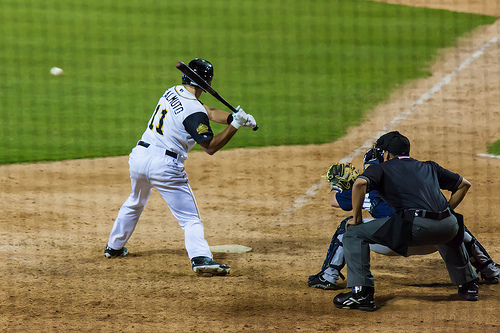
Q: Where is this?
A: This is at the field.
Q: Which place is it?
A: It is a field.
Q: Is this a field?
A: Yes, it is a field.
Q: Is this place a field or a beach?
A: It is a field.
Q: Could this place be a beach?
A: No, it is a field.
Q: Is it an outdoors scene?
A: Yes, it is outdoors.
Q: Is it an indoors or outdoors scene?
A: It is outdoors.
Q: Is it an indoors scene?
A: No, it is outdoors.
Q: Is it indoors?
A: No, it is outdoors.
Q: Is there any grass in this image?
A: Yes, there is grass.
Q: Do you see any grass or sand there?
A: Yes, there is grass.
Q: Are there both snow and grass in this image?
A: No, there is grass but no snow.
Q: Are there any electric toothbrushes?
A: No, there are no electric toothbrushes.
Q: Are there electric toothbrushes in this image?
A: No, there are no electric toothbrushes.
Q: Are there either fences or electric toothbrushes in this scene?
A: No, there are no electric toothbrushes or fences.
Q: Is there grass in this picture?
A: Yes, there is grass.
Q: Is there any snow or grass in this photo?
A: Yes, there is grass.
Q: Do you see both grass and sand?
A: No, there is grass but no sand.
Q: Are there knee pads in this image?
A: No, there are no knee pads.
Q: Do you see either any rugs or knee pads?
A: No, there are no knee pads or rugs.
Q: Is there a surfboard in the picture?
A: No, there are no surfboards.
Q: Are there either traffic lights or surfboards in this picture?
A: No, there are no surfboards or traffic lights.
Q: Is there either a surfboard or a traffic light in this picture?
A: No, there are no surfboards or traffic lights.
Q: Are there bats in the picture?
A: Yes, there is a bat.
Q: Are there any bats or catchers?
A: Yes, there is a bat.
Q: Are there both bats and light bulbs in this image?
A: No, there is a bat but no light bulbs.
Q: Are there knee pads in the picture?
A: No, there are no knee pads.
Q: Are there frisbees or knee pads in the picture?
A: No, there are no knee pads or frisbees.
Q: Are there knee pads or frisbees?
A: No, there are no knee pads or frisbees.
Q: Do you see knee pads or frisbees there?
A: No, there are no knee pads or frisbees.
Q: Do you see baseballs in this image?
A: Yes, there is a baseball.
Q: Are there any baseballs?
A: Yes, there is a baseball.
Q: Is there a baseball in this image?
A: Yes, there is a baseball.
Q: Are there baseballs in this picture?
A: Yes, there is a baseball.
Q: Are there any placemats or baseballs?
A: Yes, there is a baseball.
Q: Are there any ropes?
A: No, there are no ropes.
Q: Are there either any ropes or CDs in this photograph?
A: No, there are no ropes or cds.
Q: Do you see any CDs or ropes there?
A: No, there are no ropes or cds.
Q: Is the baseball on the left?
A: Yes, the baseball is on the left of the image.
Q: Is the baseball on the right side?
A: No, the baseball is on the left of the image.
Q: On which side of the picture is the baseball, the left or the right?
A: The baseball is on the left of the image.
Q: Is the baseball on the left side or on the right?
A: The baseball is on the left of the image.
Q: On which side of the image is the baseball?
A: The baseball is on the left of the image.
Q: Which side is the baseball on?
A: The baseball is on the left of the image.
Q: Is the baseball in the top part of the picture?
A: Yes, the baseball is in the top of the image.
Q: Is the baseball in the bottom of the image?
A: No, the baseball is in the top of the image.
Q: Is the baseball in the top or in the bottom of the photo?
A: The baseball is in the top of the image.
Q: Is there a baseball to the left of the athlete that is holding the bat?
A: Yes, there is a baseball to the left of the athlete.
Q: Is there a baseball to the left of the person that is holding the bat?
A: Yes, there is a baseball to the left of the athlete.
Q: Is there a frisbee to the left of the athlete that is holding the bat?
A: No, there is a baseball to the left of the athlete.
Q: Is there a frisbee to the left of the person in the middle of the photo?
A: No, there is a baseball to the left of the athlete.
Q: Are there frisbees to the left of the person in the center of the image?
A: No, there is a baseball to the left of the athlete.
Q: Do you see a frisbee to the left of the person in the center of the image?
A: No, there is a baseball to the left of the athlete.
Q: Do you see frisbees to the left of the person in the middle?
A: No, there is a baseball to the left of the athlete.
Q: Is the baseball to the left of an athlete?
A: Yes, the baseball is to the left of an athlete.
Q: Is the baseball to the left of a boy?
A: No, the baseball is to the left of an athlete.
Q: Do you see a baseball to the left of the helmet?
A: Yes, there is a baseball to the left of the helmet.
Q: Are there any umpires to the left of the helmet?
A: No, there is a baseball to the left of the helmet.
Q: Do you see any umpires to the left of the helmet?
A: No, there is a baseball to the left of the helmet.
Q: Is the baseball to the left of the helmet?
A: Yes, the baseball is to the left of the helmet.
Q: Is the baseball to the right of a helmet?
A: No, the baseball is to the left of a helmet.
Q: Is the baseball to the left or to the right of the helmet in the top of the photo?
A: The baseball is to the left of the helmet.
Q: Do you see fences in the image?
A: No, there are no fences.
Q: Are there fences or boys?
A: No, there are no fences or boys.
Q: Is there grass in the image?
A: Yes, there is grass.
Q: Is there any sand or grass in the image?
A: Yes, there is grass.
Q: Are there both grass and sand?
A: No, there is grass but no sand.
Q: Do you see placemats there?
A: No, there are no placemats.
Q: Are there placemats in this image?
A: No, there are no placemats.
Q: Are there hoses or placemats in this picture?
A: No, there are no placemats or hoses.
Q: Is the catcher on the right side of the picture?
A: Yes, the catcher is on the right of the image.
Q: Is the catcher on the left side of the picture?
A: No, the catcher is on the right of the image.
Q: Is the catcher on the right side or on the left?
A: The catcher is on the right of the image.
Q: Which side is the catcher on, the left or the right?
A: The catcher is on the right of the image.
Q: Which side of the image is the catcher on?
A: The catcher is on the right of the image.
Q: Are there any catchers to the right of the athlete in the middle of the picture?
A: Yes, there is a catcher to the right of the athlete.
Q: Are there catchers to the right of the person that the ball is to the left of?
A: Yes, there is a catcher to the right of the athlete.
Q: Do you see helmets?
A: Yes, there is a helmet.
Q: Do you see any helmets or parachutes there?
A: Yes, there is a helmet.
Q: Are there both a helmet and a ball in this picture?
A: Yes, there are both a helmet and a ball.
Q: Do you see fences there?
A: No, there are no fences.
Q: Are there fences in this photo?
A: No, there are no fences.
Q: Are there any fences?
A: No, there are no fences.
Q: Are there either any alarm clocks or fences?
A: No, there are no fences or alarm clocks.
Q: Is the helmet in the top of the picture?
A: Yes, the helmet is in the top of the image.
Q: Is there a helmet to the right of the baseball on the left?
A: Yes, there is a helmet to the right of the baseball.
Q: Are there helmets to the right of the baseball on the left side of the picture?
A: Yes, there is a helmet to the right of the baseball.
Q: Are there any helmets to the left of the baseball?
A: No, the helmet is to the right of the baseball.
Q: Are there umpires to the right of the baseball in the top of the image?
A: No, there is a helmet to the right of the baseball.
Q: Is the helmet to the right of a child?
A: No, the helmet is to the right of a baseball.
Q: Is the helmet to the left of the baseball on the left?
A: No, the helmet is to the right of the baseball.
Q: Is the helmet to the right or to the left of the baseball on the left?
A: The helmet is to the right of the baseball.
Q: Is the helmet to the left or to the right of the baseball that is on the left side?
A: The helmet is to the right of the baseball.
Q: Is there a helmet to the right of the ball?
A: Yes, there is a helmet to the right of the ball.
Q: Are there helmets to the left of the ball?
A: No, the helmet is to the right of the ball.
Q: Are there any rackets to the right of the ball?
A: No, there is a helmet to the right of the ball.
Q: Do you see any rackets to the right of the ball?
A: No, there is a helmet to the right of the ball.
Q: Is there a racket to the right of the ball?
A: No, there is a helmet to the right of the ball.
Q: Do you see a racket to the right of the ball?
A: No, there is a helmet to the right of the ball.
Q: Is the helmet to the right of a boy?
A: No, the helmet is to the right of the ball.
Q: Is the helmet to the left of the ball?
A: No, the helmet is to the right of the ball.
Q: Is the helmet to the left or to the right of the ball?
A: The helmet is to the right of the ball.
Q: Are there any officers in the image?
A: No, there are no officers.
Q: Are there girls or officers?
A: No, there are no officers or girls.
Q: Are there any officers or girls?
A: No, there are no officers or girls.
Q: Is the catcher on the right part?
A: Yes, the catcher is on the right of the image.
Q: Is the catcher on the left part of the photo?
A: No, the catcher is on the right of the image.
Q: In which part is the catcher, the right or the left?
A: The catcher is on the right of the image.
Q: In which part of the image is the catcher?
A: The catcher is on the right of the image.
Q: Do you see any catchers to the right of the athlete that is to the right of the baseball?
A: Yes, there is a catcher to the right of the athlete.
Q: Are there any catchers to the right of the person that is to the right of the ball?
A: Yes, there is a catcher to the right of the athlete.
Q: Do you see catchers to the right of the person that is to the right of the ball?
A: Yes, there is a catcher to the right of the athlete.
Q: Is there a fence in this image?
A: No, there are no fences.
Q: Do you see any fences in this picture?
A: No, there are no fences.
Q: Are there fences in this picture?
A: No, there are no fences.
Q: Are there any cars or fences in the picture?
A: No, there are no fences or cars.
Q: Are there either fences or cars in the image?
A: No, there are no fences or cars.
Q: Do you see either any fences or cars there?
A: No, there are no fences or cars.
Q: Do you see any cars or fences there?
A: No, there are no fences or cars.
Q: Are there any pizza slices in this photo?
A: No, there are no pizza slices.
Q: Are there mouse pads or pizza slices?
A: No, there are no pizza slices or mouse pads.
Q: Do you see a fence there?
A: No, there are no fences.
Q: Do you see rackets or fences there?
A: No, there are no fences or rackets.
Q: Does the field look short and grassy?
A: Yes, the field is short and grassy.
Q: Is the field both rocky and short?
A: No, the field is short but grassy.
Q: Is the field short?
A: Yes, the field is short.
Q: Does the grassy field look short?
A: Yes, the field is short.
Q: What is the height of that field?
A: The field is short.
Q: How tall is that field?
A: The field is short.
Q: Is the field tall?
A: No, the field is short.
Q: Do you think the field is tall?
A: No, the field is short.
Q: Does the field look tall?
A: No, the field is short.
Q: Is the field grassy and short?
A: Yes, the field is grassy and short.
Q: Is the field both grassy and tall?
A: No, the field is grassy but short.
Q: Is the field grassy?
A: Yes, the field is grassy.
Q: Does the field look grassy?
A: Yes, the field is grassy.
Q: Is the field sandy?
A: No, the field is grassy.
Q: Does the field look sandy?
A: No, the field is grassy.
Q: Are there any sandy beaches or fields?
A: No, there is a field but it is grassy.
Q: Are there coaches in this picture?
A: No, there are no coaches.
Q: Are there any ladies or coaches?
A: No, there are no coaches or ladies.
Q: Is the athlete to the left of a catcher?
A: Yes, the athlete is to the left of a catcher.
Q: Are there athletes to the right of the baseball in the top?
A: Yes, there is an athlete to the right of the baseball.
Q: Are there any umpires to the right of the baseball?
A: No, there is an athlete to the right of the baseball.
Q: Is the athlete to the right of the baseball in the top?
A: Yes, the athlete is to the right of the baseball.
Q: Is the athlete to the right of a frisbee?
A: No, the athlete is to the right of the baseball.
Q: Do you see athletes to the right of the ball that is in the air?
A: Yes, there is an athlete to the right of the ball.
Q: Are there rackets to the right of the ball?
A: No, there is an athlete to the right of the ball.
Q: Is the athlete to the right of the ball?
A: Yes, the athlete is to the right of the ball.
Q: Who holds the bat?
A: The athlete holds the bat.